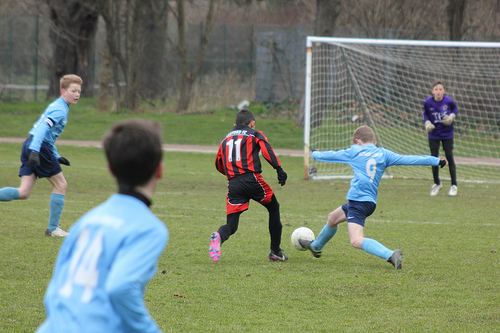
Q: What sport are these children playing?
A: Soccer.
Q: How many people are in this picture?
A: Five.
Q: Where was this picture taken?
A: Soccer field.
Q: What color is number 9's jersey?
A: Blue.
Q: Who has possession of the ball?
A: Number 9.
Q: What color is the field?
A: Green.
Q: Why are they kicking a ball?
A: They are playing soccer.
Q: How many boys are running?
A: 4.